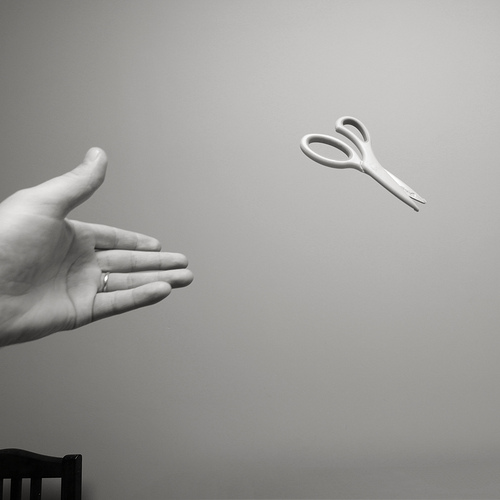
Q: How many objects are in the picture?
A: Three.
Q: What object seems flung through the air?
A: Scissors.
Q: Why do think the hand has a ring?
A: Marriage.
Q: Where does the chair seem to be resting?
A: On the floor.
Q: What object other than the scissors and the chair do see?
A: A hand.